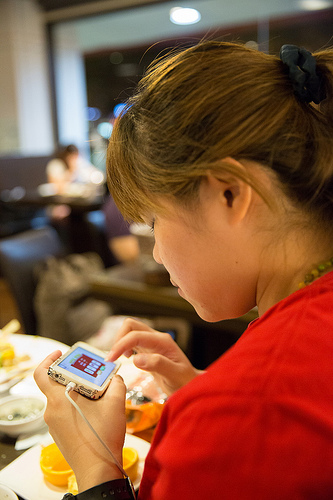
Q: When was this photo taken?
A: During the day.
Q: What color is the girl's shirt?
A: Red.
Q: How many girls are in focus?
A: One.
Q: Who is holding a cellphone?
A: The girl.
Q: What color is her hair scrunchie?
A: Black.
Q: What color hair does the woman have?
A: Brown.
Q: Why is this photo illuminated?
A: A light fixture.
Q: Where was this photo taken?
A: In a cafeteria.